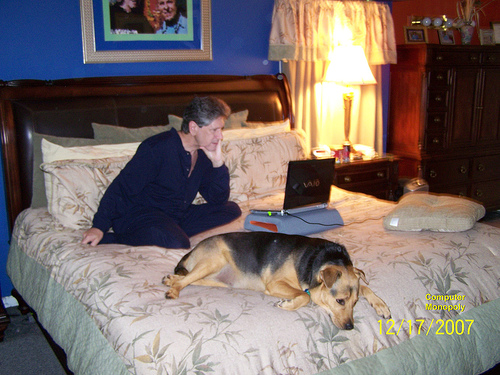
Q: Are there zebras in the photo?
A: No, there are no zebras.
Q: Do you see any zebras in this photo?
A: No, there are no zebras.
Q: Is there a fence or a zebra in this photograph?
A: No, there are no zebras or fences.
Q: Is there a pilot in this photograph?
A: No, there are no pilots.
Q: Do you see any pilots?
A: No, there are no pilots.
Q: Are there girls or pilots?
A: No, there are no pilots or girls.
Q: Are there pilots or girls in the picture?
A: No, there are no pilots or girls.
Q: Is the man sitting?
A: Yes, the man is sitting.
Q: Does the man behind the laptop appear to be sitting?
A: Yes, the man is sitting.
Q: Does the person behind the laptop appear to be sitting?
A: Yes, the man is sitting.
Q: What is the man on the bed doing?
A: The man is sitting.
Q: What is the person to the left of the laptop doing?
A: The man is sitting.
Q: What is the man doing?
A: The man is sitting.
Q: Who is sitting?
A: The man is sitting.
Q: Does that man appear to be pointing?
A: No, the man is sitting.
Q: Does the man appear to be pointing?
A: No, the man is sitting.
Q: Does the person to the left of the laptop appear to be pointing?
A: No, the man is sitting.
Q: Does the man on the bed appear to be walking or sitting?
A: The man is sitting.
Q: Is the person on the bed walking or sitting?
A: The man is sitting.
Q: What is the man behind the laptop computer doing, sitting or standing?
A: The man is sitting.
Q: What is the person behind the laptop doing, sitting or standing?
A: The man is sitting.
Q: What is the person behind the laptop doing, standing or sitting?
A: The man is sitting.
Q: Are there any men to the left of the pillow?
A: Yes, there is a man to the left of the pillow.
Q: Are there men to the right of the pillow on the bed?
A: No, the man is to the left of the pillow.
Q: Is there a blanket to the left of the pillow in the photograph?
A: No, there is a man to the left of the pillow.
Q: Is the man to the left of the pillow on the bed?
A: Yes, the man is to the left of the pillow.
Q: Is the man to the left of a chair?
A: No, the man is to the left of the pillow.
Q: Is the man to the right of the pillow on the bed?
A: No, the man is to the left of the pillow.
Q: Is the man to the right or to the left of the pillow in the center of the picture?
A: The man is to the left of the pillow.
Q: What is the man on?
A: The man is on the bed.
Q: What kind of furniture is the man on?
A: The man is on the bed.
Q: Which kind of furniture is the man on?
A: The man is on the bed.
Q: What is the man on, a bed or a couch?
A: The man is on a bed.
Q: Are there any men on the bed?
A: Yes, there is a man on the bed.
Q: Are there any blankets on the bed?
A: No, there is a man on the bed.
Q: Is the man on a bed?
A: Yes, the man is on a bed.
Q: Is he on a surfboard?
A: No, the man is on a bed.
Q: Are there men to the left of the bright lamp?
A: Yes, there is a man to the left of the lamp.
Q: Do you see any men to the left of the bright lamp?
A: Yes, there is a man to the left of the lamp.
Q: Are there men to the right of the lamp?
A: No, the man is to the left of the lamp.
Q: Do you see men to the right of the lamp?
A: No, the man is to the left of the lamp.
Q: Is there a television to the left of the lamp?
A: No, there is a man to the left of the lamp.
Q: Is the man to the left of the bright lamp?
A: Yes, the man is to the left of the lamp.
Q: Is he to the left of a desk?
A: No, the man is to the left of the lamp.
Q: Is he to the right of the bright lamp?
A: No, the man is to the left of the lamp.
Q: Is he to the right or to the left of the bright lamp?
A: The man is to the left of the lamp.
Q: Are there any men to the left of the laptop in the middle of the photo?
A: Yes, there is a man to the left of the laptop.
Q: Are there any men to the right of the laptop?
A: No, the man is to the left of the laptop.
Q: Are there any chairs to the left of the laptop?
A: No, there is a man to the left of the laptop.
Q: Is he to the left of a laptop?
A: Yes, the man is to the left of a laptop.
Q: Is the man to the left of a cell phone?
A: No, the man is to the left of a laptop.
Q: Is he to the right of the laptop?
A: No, the man is to the left of the laptop.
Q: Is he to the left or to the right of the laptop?
A: The man is to the left of the laptop.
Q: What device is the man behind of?
A: The man is behind the laptop.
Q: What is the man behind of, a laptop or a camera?
A: The man is behind a laptop.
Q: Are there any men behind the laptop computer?
A: Yes, there is a man behind the laptop computer.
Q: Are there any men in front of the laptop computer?
A: No, the man is behind the laptop computer.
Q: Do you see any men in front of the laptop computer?
A: No, the man is behind the laptop computer.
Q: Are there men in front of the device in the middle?
A: No, the man is behind the laptop computer.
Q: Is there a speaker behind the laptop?
A: No, there is a man behind the laptop.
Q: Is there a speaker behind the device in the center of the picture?
A: No, there is a man behind the laptop.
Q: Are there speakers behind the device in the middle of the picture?
A: No, there is a man behind the laptop.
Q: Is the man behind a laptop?
A: Yes, the man is behind a laptop.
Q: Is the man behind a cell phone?
A: No, the man is behind a laptop.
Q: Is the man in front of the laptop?
A: No, the man is behind the laptop.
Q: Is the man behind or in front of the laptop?
A: The man is behind the laptop.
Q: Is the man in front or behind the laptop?
A: The man is behind the laptop.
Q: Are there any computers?
A: Yes, there is a computer.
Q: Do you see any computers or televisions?
A: Yes, there is a computer.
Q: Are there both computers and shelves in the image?
A: No, there is a computer but no shelves.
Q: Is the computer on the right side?
A: Yes, the computer is on the right of the image.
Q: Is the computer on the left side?
A: No, the computer is on the right of the image.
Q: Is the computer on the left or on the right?
A: The computer is on the right of the image.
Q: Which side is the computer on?
A: The computer is on the right of the image.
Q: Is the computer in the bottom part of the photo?
A: Yes, the computer is in the bottom of the image.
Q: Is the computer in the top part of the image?
A: No, the computer is in the bottom of the image.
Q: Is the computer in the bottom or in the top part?
A: The computer is in the bottom of the image.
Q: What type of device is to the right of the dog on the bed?
A: The device is a computer.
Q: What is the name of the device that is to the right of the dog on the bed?
A: The device is a computer.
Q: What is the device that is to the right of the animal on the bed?
A: The device is a computer.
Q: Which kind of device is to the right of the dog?
A: The device is a computer.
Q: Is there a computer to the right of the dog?
A: Yes, there is a computer to the right of the dog.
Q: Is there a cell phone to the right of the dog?
A: No, there is a computer to the right of the dog.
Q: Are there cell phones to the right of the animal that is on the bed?
A: No, there is a computer to the right of the dog.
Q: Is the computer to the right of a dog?
A: Yes, the computer is to the right of a dog.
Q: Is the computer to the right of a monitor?
A: No, the computer is to the right of a dog.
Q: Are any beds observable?
A: Yes, there is a bed.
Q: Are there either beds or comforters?
A: Yes, there is a bed.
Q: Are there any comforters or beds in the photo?
A: Yes, there is a bed.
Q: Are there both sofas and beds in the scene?
A: No, there is a bed but no sofas.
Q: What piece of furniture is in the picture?
A: The piece of furniture is a bed.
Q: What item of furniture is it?
A: The piece of furniture is a bed.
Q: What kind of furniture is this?
A: This is a bed.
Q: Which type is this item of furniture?
A: This is a bed.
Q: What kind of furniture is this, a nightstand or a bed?
A: This is a bed.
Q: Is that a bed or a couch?
A: That is a bed.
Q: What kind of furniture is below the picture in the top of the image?
A: The piece of furniture is a bed.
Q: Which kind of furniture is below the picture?
A: The piece of furniture is a bed.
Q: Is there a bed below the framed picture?
A: Yes, there is a bed below the picture.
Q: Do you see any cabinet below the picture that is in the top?
A: No, there is a bed below the picture.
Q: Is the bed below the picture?
A: Yes, the bed is below the picture.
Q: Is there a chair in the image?
A: No, there are no chairs.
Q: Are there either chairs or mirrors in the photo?
A: No, there are no chairs or mirrors.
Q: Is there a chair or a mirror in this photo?
A: No, there are no chairs or mirrors.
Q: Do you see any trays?
A: No, there are no trays.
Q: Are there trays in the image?
A: No, there are no trays.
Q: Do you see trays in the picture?
A: No, there are no trays.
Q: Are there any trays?
A: No, there are no trays.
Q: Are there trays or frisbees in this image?
A: No, there are no trays or frisbees.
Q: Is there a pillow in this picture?
A: Yes, there is a pillow.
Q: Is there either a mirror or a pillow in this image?
A: Yes, there is a pillow.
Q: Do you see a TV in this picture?
A: No, there are no televisions.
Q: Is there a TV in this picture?
A: No, there are no televisions.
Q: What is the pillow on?
A: The pillow is on the bed.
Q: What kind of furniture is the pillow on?
A: The pillow is on the bed.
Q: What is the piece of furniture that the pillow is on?
A: The piece of furniture is a bed.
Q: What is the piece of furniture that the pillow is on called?
A: The piece of furniture is a bed.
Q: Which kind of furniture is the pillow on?
A: The pillow is on the bed.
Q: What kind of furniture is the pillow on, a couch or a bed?
A: The pillow is on a bed.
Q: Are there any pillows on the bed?
A: Yes, there is a pillow on the bed.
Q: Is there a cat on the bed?
A: No, there is a pillow on the bed.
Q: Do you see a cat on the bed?
A: No, there is a pillow on the bed.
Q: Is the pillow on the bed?
A: Yes, the pillow is on the bed.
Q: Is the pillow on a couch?
A: No, the pillow is on the bed.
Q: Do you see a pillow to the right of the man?
A: Yes, there is a pillow to the right of the man.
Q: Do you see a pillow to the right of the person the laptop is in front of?
A: Yes, there is a pillow to the right of the man.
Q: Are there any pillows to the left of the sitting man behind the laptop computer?
A: No, the pillow is to the right of the man.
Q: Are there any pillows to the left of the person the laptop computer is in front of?
A: No, the pillow is to the right of the man.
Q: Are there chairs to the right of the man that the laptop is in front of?
A: No, there is a pillow to the right of the man.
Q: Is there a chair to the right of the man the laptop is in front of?
A: No, there is a pillow to the right of the man.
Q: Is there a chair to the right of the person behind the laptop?
A: No, there is a pillow to the right of the man.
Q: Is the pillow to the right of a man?
A: Yes, the pillow is to the right of a man.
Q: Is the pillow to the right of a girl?
A: No, the pillow is to the right of a man.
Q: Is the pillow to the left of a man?
A: No, the pillow is to the right of a man.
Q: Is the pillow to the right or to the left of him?
A: The pillow is to the right of the man.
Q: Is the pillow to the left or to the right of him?
A: The pillow is to the right of the man.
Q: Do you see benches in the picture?
A: No, there are no benches.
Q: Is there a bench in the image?
A: No, there are no benches.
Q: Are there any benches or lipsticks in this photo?
A: No, there are no benches or lipsticks.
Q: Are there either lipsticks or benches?
A: No, there are no benches or lipsticks.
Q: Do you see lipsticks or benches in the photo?
A: No, there are no benches or lipsticks.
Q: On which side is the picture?
A: The picture is on the left of the image.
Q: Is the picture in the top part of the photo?
A: Yes, the picture is in the top of the image.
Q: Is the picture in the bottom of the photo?
A: No, the picture is in the top of the image.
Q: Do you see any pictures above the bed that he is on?
A: Yes, there is a picture above the bed.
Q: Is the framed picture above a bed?
A: Yes, the picture is above a bed.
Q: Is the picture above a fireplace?
A: No, the picture is above a bed.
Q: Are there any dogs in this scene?
A: Yes, there is a dog.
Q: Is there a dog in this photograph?
A: Yes, there is a dog.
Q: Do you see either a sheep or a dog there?
A: Yes, there is a dog.